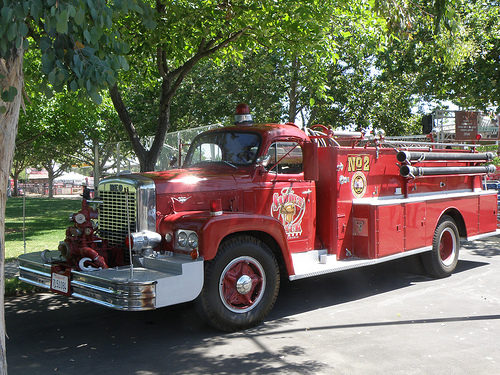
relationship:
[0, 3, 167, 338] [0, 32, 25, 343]
tree has trunk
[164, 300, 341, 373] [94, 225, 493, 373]
shadow on road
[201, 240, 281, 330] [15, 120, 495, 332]
tire on engine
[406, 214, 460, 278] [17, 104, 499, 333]
tire on engine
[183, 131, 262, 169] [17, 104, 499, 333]
windshield on engine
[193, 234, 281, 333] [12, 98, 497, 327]
tire on firetruck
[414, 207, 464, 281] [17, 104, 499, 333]
tire on engine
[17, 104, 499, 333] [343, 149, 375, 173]
engine number no2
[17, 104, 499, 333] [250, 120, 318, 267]
engine has door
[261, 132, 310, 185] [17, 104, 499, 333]
window has engine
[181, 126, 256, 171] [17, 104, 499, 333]
windshield on engine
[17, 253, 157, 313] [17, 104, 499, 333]
bumper on engine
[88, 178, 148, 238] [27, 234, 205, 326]
grill on truck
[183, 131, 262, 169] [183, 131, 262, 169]
windshield on windshield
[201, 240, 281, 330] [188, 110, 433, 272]
tire on fire truck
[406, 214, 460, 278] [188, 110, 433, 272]
tire on fire truck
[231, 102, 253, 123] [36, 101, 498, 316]
light on truck